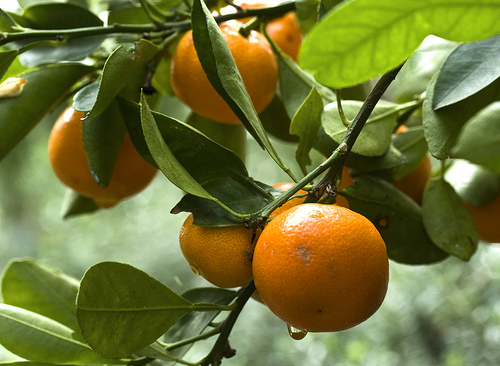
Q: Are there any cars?
A: No, there are no cars.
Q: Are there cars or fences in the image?
A: No, there are no cars or fences.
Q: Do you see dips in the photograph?
A: No, there are no dips.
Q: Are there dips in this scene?
A: No, there are no dips.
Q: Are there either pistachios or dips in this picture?
A: No, there are no dips or pistachios.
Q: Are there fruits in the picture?
A: Yes, there is a fruit.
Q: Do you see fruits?
A: Yes, there is a fruit.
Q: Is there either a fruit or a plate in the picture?
A: Yes, there is a fruit.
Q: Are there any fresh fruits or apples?
A: Yes, there is a fresh fruit.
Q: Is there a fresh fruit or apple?
A: Yes, there is a fresh fruit.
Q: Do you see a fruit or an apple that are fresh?
A: Yes, the fruit is fresh.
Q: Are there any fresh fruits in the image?
A: Yes, there is a fresh fruit.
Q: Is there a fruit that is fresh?
A: Yes, there is a fruit that is fresh.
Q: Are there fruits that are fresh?
A: Yes, there is a fruit that is fresh.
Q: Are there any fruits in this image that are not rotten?
A: Yes, there is a fresh fruit.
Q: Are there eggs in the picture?
A: No, there are no eggs.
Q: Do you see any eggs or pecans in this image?
A: No, there are no eggs or pecans.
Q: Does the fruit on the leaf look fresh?
A: Yes, the fruit is fresh.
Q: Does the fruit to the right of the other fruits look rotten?
A: No, the fruit is fresh.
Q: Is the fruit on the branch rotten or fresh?
A: The fruit is fresh.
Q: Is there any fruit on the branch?
A: Yes, there is a fruit on the branch.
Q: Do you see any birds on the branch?
A: No, there is a fruit on the branch.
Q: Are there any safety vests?
A: No, there are no safety vests.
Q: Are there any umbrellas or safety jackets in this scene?
A: No, there are no safety jackets or umbrellas.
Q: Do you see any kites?
A: No, there are no kites.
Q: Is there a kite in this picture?
A: No, there are no kites.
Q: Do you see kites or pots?
A: No, there are no kites or pots.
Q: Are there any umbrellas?
A: No, there are no umbrellas.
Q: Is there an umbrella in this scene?
A: No, there are no umbrellas.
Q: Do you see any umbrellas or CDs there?
A: No, there are no umbrellas or cds.